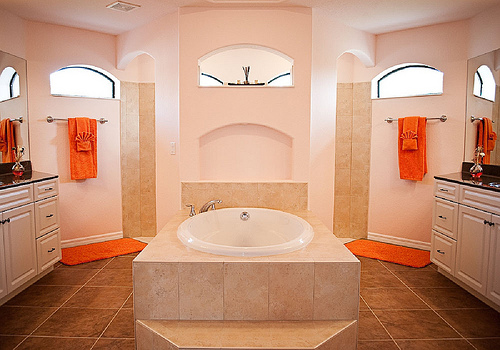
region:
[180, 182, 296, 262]
white tub and silver nozzle.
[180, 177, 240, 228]
silver faucet outside bath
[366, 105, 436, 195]
orange towel hanging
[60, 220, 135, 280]
orange mat on the floor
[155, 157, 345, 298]
tub in the room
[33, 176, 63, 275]
droors in the bathroom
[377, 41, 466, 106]
window above the towel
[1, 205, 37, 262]
cabinets under the sink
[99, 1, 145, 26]
vent above the ground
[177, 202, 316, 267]
white circular bath tub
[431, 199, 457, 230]
small white drawer with a dark handle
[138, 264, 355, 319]
five beige marble tiles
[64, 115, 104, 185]
orange towels hanging over the rack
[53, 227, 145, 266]
fluffy orange bath mat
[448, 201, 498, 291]
white cabinet door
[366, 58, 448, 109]
window with light streaming in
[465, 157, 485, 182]
round bottle half filled with liquid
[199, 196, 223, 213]
silver faucet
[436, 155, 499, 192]
shiny dark countertop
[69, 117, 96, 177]
orange towel from rack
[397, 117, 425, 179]
orange towel hanging from rack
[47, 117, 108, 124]
silver rack on wall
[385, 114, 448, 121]
silver rack with towel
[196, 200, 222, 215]
tub faucet is silver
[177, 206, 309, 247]
round, white tub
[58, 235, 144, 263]
orange rug on the floor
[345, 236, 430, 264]
orange rug to right of tub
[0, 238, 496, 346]
tiled, patterned on floor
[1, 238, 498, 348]
floor is brown in color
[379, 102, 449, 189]
orange towels on rack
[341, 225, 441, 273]
orange rug on floor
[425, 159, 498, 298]
vanity with wood cabinets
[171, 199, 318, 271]
white tub with silver fixtures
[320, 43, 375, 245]
arched doorway in bathroom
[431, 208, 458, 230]
handle on vanity drawer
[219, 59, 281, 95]
decoartion in arched window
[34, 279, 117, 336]
brown tiles on floor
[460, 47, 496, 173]
mirror on bathroom wall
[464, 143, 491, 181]
vase on vanity counter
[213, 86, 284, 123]
this is a wall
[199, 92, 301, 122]
the wall is white in color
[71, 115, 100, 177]
this is a towel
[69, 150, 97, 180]
the towel is orange in color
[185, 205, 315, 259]
this is a bath tub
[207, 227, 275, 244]
the bath tub is white in color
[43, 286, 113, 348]
this is the floor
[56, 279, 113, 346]
the floor is made of tiles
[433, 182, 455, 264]
these are the drawers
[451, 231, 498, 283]
the drawers are white in color